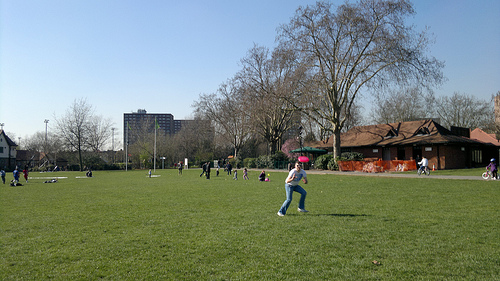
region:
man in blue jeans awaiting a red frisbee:
[275, 146, 323, 211]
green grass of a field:
[87, 195, 252, 264]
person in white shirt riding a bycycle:
[407, 148, 434, 178]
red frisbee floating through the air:
[295, 145, 309, 165]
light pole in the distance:
[35, 115, 59, 147]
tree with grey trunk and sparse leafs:
[267, 15, 389, 159]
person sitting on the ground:
[249, 165, 270, 186]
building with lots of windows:
[116, 101, 201, 158]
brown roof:
[345, 119, 443, 153]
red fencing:
[339, 159, 414, 180]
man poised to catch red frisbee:
[271, 139, 317, 220]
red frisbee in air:
[261, 146, 323, 219]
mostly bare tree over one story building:
[275, 5, 428, 174]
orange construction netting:
[331, 147, 416, 181]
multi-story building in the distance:
[117, 108, 214, 174]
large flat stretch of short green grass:
[42, 197, 244, 262]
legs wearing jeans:
[269, 185, 314, 217]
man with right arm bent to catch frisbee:
[274, 149, 319, 221]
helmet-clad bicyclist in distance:
[467, 147, 497, 198]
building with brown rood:
[338, 108, 462, 144]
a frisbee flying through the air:
[291, 143, 316, 173]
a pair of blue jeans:
[273, 184, 309, 211]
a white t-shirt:
[284, 170, 310, 186]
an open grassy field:
[0, 178, 493, 271]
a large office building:
[108, 111, 233, 164]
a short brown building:
[287, 122, 476, 174]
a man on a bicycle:
[410, 151, 446, 174]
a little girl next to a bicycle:
[472, 156, 499, 183]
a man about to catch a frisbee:
[264, 169, 346, 219]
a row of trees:
[170, 78, 348, 163]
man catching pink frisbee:
[276, 141, 326, 241]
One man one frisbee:
[261, 130, 331, 228]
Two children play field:
[229, 165, 252, 185]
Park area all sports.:
[2, 148, 198, 265]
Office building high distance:
[122, 107, 220, 163]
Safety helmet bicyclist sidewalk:
[472, 155, 498, 182]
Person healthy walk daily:
[407, 151, 446, 173]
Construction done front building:
[337, 155, 417, 175]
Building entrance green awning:
[287, 142, 330, 168]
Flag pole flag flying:
[146, 114, 162, 171]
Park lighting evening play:
[38, 114, 60, 164]